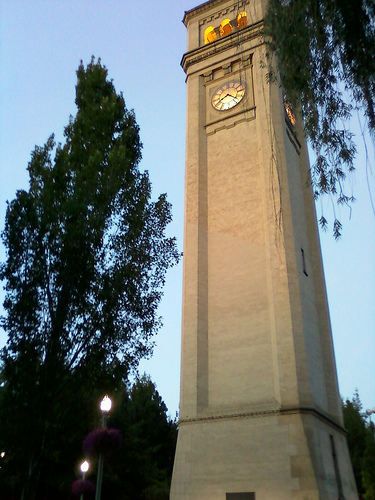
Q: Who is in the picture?
A: No one.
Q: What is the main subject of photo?
A: Clock tower.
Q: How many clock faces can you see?
A: 2.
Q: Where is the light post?
A: To the left of the clock tower.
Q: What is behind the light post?
A: Trees.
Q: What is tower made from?
A: Concrete.